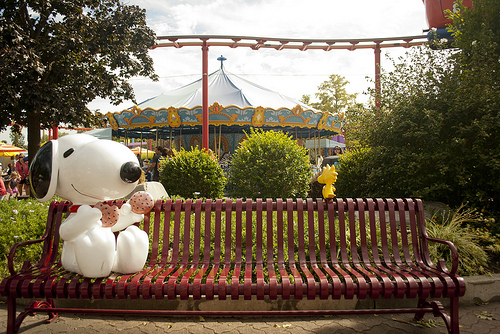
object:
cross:
[216, 55, 227, 68]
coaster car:
[423, 0, 500, 50]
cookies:
[91, 202, 120, 228]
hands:
[75, 206, 102, 230]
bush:
[157, 144, 224, 198]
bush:
[225, 126, 314, 201]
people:
[14, 153, 31, 196]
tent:
[0, 140, 29, 158]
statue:
[315, 163, 338, 201]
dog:
[25, 133, 155, 280]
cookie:
[128, 192, 155, 214]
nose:
[119, 160, 142, 184]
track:
[142, 27, 454, 50]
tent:
[96, 54, 344, 141]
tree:
[0, 0, 161, 164]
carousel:
[94, 53, 347, 189]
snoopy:
[26, 133, 156, 278]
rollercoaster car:
[422, 0, 490, 51]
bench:
[0, 196, 464, 334]